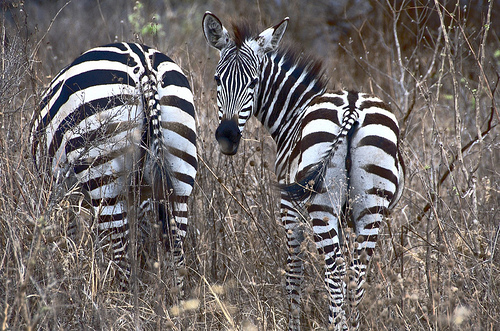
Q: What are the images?
A: Zebras.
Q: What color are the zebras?
A: Black and white.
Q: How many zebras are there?
A: Two.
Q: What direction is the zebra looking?
A: At the camera.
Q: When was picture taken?
A: Daytime.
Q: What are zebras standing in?
A: Brush.